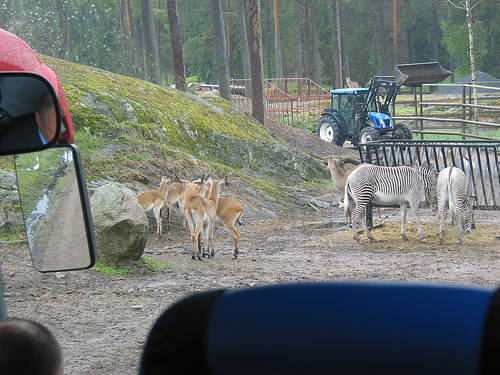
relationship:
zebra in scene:
[338, 165, 429, 243] [1, 1, 499, 374]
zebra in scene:
[433, 165, 480, 248] [1, 1, 499, 374]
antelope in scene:
[179, 175, 225, 262] [1, 1, 499, 374]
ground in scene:
[1, 46, 499, 374] [1, 1, 499, 374]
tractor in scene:
[315, 72, 416, 154] [1, 1, 499, 374]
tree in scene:
[239, 1, 269, 124] [1, 1, 499, 374]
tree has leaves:
[437, 1, 499, 113] [440, 17, 494, 78]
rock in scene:
[85, 178, 149, 258] [1, 1, 499, 374]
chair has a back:
[126, 277, 498, 375] [136, 284, 497, 375]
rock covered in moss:
[2, 48, 332, 242] [41, 55, 291, 195]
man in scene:
[6, 88, 63, 147] [1, 1, 499, 374]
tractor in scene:
[315, 60, 457, 153] [1, 1, 499, 374]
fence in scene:
[378, 73, 499, 143] [1, 1, 499, 374]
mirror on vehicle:
[13, 147, 102, 278] [1, 19, 499, 374]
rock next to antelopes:
[85, 178, 149, 258] [134, 168, 251, 262]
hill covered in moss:
[2, 48, 332, 242] [41, 55, 291, 195]